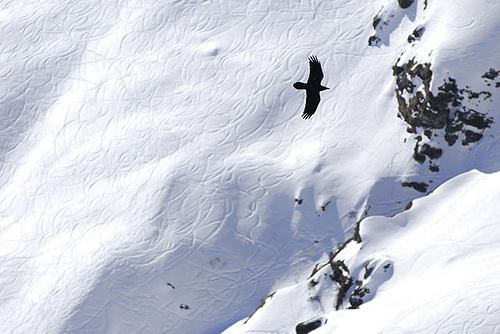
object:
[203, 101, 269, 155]
lines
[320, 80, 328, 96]
beak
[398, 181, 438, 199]
rock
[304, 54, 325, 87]
bird wing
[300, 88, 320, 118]
bird wing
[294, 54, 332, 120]
bird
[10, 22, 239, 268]
snow/covered ground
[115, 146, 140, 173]
swirl pattern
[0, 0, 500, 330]
mountain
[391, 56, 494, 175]
rock portions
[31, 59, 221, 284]
white snow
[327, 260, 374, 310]
rocks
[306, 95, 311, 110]
wing edge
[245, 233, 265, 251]
lines part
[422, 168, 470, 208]
hill edge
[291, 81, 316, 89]
tail/wing part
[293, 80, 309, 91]
bird back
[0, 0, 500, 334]
winter scene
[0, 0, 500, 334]
snow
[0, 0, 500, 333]
landscape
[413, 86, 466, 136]
spot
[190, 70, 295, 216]
snow tracks